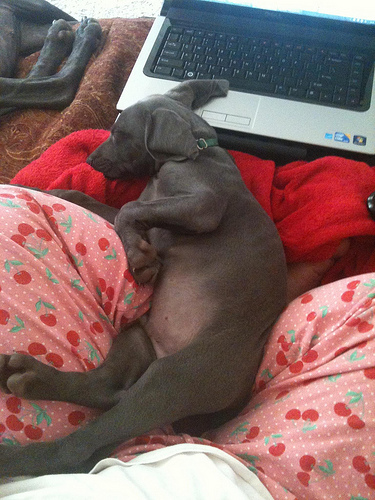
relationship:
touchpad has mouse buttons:
[198, 88, 263, 135] [199, 109, 254, 130]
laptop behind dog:
[115, 0, 374, 170] [1, 77, 291, 479]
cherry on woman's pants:
[97, 235, 121, 264] [0, 183, 374, 500]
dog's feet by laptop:
[39, 14, 104, 56] [115, 0, 374, 170]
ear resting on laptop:
[167, 73, 233, 110] [115, 0, 374, 170]